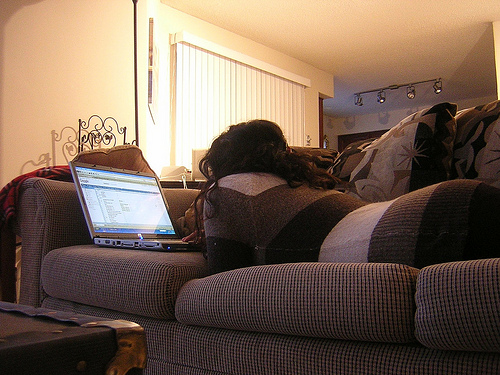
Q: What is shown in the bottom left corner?
A: The edge of the trunk on the floor.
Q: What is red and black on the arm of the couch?
A: The blanket.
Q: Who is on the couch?
A: A woman wearing a striped sweater.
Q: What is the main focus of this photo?
A: A lady looking at a laptop.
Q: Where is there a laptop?
A: On a couch.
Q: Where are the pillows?
A: On a couch.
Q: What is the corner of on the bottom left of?
A: A trunk coffee table.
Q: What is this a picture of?
A: The woman.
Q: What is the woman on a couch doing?
A: Using the laptop.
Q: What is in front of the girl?
A: A laptop.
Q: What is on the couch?
A: A girl.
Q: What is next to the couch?
A: A table.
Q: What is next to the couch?
A: A table.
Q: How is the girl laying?
A: On her stomach.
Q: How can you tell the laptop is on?
A: It emits light.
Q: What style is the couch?
A: Checkered.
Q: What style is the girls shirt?
A: Striped.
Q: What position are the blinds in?
A: Closed.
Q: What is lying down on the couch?
A: A woman.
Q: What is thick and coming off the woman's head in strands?
A: Hair.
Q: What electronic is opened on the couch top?
A: Laptop.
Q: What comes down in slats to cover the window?
A: Blinds.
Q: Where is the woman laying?
A: On the couch.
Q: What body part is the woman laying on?
A: Stomach.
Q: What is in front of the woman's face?
A: Laptop.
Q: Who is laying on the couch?
A: A woman.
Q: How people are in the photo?
A: 1.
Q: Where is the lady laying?
A: On the couch.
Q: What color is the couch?
A: Gray.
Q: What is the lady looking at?
A: The computer screen.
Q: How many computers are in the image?
A: 1.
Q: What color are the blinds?
A: White.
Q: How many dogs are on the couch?
A: 0.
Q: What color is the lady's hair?
A: Black.